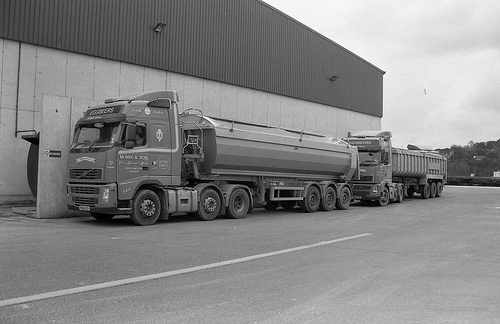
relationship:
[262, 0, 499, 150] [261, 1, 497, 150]
cloud in sky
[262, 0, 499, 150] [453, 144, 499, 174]
cloud above mountains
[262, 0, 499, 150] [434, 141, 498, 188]
cloud above mountains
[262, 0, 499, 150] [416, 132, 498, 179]
cloud above mountains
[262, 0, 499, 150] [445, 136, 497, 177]
cloud above mountains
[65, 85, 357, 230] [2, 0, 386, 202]
truck in front of building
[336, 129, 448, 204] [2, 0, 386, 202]
truck in front of building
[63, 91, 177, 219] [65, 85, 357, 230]
cab of truck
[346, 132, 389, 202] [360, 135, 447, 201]
cab of truck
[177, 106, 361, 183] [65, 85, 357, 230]
tanker of truck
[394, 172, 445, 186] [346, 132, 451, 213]
bed of dump truck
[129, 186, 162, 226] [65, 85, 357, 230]
wheel of a truck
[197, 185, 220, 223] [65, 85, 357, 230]
wheel of a truck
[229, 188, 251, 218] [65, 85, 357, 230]
wheel of a truck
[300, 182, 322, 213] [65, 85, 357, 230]
wheel of a truck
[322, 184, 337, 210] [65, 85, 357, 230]
wheel of a truck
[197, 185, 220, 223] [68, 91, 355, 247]
wheel of a truck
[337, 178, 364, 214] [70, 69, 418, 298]
wheel of a truck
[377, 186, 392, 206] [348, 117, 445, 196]
wheel of a truck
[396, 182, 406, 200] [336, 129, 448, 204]
rubber wheel of a truck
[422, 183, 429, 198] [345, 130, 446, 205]
wheel of a truck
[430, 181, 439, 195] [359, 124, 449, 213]
wheel of a truck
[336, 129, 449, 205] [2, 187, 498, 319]
truck on road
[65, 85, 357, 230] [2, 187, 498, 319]
truck on road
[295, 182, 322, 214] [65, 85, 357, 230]
wheel on back of truck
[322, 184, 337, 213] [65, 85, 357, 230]
wheel on back of truck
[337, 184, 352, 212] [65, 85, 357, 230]
wheel on back of truck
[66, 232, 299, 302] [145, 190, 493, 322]
line on road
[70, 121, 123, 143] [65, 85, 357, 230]
windshield on truck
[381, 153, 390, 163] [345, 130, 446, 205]
mirror on side of truck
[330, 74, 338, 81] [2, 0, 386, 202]
light high up on building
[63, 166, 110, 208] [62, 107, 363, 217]
vents on front of truck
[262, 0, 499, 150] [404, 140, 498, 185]
cloud above mountains